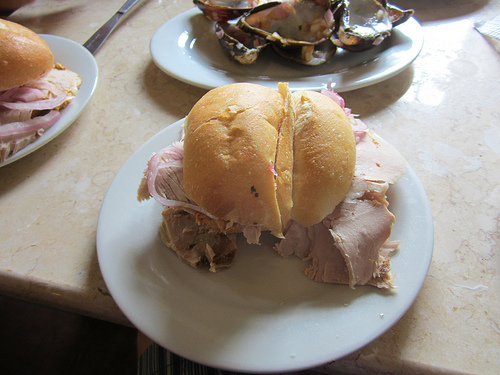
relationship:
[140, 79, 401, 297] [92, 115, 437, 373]
sandwich on plate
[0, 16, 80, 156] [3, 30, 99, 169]
sandwich on plate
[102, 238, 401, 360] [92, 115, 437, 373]
shadow on plate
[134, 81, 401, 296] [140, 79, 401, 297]
meat on sandwich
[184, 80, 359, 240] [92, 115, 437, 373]
bread on plate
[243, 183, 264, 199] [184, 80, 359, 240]
spot on bread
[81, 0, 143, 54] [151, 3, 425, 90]
utensil next to plate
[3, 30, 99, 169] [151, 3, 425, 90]
plate next to plate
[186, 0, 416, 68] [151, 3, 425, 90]
food on plate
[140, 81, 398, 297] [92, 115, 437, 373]
food on plate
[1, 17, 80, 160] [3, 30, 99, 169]
food on plate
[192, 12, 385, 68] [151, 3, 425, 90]
shells on plate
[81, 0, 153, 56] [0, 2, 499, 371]
knife on table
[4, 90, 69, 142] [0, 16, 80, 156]
onion slices on sandwich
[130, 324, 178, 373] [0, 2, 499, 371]
leg on table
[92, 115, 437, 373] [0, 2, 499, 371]
plate on table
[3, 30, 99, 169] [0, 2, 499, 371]
plate on table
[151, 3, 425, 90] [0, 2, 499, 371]
plate on table